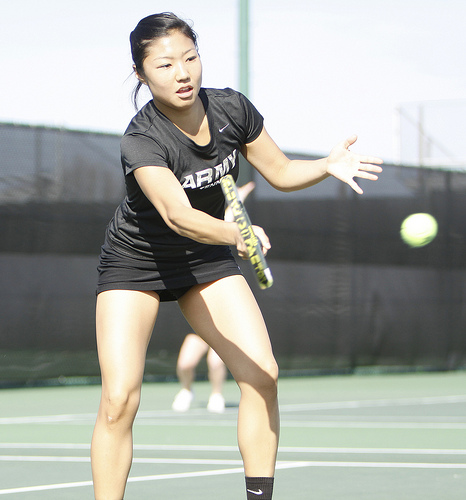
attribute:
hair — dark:
[129, 11, 198, 105]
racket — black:
[222, 166, 274, 293]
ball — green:
[403, 212, 438, 248]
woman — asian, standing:
[93, 14, 383, 497]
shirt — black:
[106, 86, 265, 259]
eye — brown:
[164, 61, 172, 71]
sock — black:
[244, 476, 274, 499]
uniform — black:
[96, 89, 263, 288]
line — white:
[17, 447, 465, 476]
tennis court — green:
[2, 371, 462, 499]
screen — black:
[1, 121, 464, 392]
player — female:
[96, 13, 385, 499]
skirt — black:
[99, 234, 241, 293]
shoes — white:
[165, 394, 193, 416]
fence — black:
[3, 123, 462, 392]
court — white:
[6, 372, 463, 499]